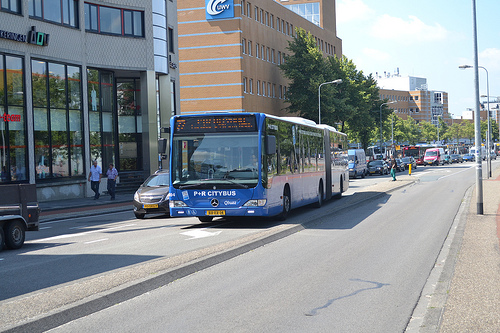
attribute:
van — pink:
[421, 147, 440, 166]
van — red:
[412, 132, 445, 172]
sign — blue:
[198, 1, 234, 30]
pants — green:
[388, 168, 398, 182]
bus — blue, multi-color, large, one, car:
[164, 109, 354, 225]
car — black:
[130, 168, 171, 218]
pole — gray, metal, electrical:
[470, 1, 483, 218]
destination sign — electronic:
[173, 114, 256, 134]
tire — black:
[279, 184, 292, 222]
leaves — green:
[305, 65, 324, 82]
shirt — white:
[86, 163, 102, 183]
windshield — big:
[170, 134, 262, 186]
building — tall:
[1, 0, 179, 220]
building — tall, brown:
[179, 2, 348, 165]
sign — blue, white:
[197, 0, 240, 23]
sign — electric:
[171, 112, 259, 135]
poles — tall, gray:
[452, 4, 483, 217]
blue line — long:
[176, 93, 246, 103]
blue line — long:
[180, 80, 242, 90]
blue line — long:
[178, 55, 245, 65]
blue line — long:
[180, 41, 240, 52]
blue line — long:
[179, 27, 239, 39]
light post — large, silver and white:
[312, 77, 344, 122]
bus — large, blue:
[167, 110, 350, 217]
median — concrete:
[39, 225, 395, 331]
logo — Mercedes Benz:
[209, 196, 222, 208]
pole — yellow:
[405, 158, 410, 168]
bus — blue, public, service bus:
[166, 101, 352, 216]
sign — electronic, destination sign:
[167, 109, 264, 138]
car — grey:
[124, 155, 173, 223]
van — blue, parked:
[342, 146, 367, 181]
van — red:
[417, 148, 442, 167]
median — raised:
[6, 260, 146, 312]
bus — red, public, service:
[400, 141, 428, 164]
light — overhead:
[461, 59, 491, 104]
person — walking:
[86, 154, 103, 200]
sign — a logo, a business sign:
[205, 3, 235, 26]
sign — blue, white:
[201, 1, 238, 26]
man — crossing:
[385, 155, 401, 187]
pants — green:
[389, 170, 399, 180]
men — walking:
[83, 159, 124, 203]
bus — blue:
[167, 116, 358, 223]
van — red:
[423, 145, 441, 165]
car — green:
[442, 152, 452, 164]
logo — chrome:
[210, 197, 220, 205]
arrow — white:
[179, 222, 220, 238]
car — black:
[132, 164, 167, 215]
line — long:
[352, 145, 470, 177]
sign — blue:
[203, 0, 236, 22]